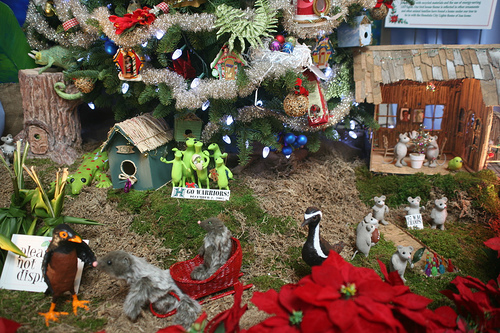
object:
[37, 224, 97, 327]
crow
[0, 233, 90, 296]
card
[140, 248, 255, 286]
turf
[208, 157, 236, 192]
figurine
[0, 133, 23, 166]
mice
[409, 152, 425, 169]
pot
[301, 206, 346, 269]
bird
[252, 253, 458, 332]
poinsettia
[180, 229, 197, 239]
grass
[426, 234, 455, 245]
grass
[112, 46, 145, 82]
teletubbies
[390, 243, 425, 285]
figurine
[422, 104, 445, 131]
window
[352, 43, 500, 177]
house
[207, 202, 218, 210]
grass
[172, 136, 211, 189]
figurine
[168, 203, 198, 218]
grass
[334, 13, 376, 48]
birdhouse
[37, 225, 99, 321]
figurine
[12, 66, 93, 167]
log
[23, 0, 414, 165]
christmas tree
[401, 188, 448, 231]
teletubbies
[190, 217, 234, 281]
skunk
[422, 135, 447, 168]
mice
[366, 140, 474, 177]
porch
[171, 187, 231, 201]
sign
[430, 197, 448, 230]
figurine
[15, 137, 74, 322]
turf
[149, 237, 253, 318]
sled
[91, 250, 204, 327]
animal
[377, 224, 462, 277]
path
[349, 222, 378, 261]
mice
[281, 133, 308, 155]
blue balls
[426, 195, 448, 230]
mouse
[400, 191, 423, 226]
mouse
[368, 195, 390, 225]
mouse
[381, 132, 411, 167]
mouse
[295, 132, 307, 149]
ornaments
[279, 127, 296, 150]
ornaments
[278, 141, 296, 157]
ornaments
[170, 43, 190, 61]
lights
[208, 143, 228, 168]
figurine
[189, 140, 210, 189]
figurine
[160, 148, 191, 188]
figurine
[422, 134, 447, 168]
figurine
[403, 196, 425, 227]
figurine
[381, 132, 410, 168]
figurine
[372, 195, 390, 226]
figurine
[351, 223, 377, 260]
figurine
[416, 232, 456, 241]
turf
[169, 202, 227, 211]
turf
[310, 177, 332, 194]
straw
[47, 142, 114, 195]
lizard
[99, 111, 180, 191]
bird house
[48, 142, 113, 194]
figurine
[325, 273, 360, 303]
center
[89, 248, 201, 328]
stuffed animal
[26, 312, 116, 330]
turf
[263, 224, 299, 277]
turf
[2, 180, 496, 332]
ground